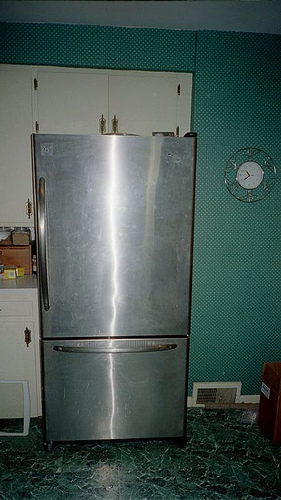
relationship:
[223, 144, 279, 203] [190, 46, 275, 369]
clock on wall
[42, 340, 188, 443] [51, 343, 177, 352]
freezer has handle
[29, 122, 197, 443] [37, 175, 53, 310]
freezer has handle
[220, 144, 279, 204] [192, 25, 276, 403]
clock mounted on wall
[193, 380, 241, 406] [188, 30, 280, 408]
air vent in wall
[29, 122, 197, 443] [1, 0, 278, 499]
freezer in house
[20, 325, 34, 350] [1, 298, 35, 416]
door handle on cabinet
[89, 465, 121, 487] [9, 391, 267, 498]
spot on tile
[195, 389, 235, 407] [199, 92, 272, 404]
vents on wall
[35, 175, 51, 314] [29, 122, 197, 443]
handle on freezer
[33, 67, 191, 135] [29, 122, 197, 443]
cabinet on freezer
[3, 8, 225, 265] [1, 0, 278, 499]
area of a house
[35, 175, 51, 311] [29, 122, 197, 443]
handle of a freezer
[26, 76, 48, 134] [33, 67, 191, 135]
hinges of cabinet